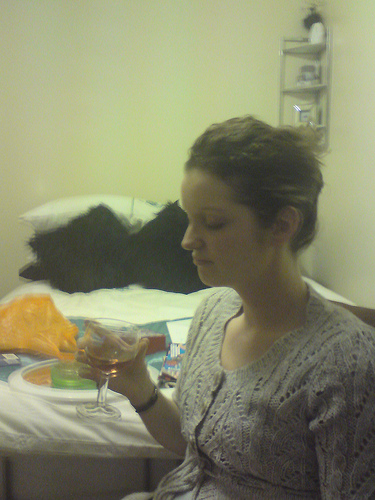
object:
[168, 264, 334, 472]
sweater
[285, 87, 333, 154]
frame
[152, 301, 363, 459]
shirt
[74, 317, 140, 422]
glass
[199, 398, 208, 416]
button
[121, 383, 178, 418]
watch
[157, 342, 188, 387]
book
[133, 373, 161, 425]
bracelet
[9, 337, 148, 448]
tray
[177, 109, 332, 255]
hair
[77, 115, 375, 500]
she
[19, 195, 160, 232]
pillow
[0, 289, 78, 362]
bag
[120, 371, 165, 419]
wrist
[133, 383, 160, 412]
watch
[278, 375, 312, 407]
holes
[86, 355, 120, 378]
wine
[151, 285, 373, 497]
sweater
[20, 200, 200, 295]
pillows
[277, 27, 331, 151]
shelf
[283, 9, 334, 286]
corner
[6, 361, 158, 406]
tray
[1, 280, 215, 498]
bed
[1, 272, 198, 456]
sheets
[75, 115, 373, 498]
woman